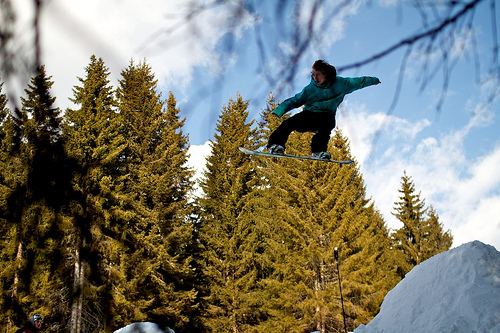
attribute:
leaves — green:
[181, 192, 306, 259]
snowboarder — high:
[232, 60, 379, 172]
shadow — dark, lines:
[16, 114, 128, 209]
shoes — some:
[260, 144, 334, 161]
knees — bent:
[266, 109, 334, 160]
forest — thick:
[5, 65, 452, 331]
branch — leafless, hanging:
[358, 0, 499, 86]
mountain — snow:
[385, 236, 499, 330]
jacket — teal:
[272, 77, 379, 116]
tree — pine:
[194, 88, 276, 331]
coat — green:
[267, 73, 383, 121]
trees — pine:
[45, 56, 198, 308]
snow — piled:
[353, 245, 498, 332]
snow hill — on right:
[348, 235, 498, 332]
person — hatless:
[256, 48, 386, 163]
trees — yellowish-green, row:
[93, 218, 221, 328]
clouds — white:
[366, 137, 450, 187]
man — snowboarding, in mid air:
[268, 60, 382, 162]